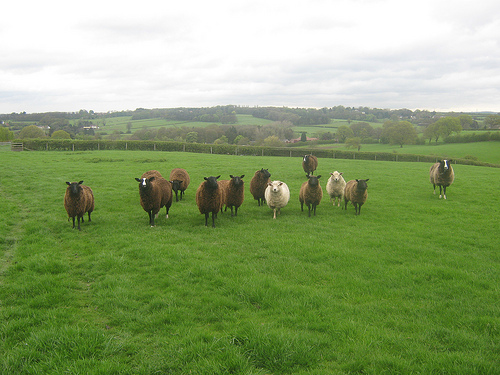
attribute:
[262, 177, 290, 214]
sheep — white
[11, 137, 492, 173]
fence — brown, wooden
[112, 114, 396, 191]
shrubs — dark green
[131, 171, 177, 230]
sheep — brown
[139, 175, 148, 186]
face — white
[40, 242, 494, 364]
pasture area — green, grassy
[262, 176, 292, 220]
sheep — white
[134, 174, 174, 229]
sheep — white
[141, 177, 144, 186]
stripe — white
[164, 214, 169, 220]
hoof — white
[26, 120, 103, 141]
house — far off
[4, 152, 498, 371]
grass — green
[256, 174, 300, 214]
sheep — brown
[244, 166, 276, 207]
sheep — black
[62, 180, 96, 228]
sheep — black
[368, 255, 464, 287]
green — healthy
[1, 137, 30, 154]
wooden gate — brown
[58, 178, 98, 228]
sheep — brown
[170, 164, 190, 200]
sheep — brown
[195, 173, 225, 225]
sheep — brown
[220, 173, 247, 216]
sheep — brown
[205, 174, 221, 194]
face — black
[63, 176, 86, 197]
head — black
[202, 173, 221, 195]
head — black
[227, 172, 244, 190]
head — black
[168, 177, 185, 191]
head — black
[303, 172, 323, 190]
head — black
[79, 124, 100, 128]
roof — red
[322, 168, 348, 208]
sheep — white, solid white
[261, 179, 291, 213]
sheep — solid white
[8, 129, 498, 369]
field — grass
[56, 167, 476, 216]
herd — walking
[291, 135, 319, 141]
roof — red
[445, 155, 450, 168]
stripe — white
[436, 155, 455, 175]
face — its